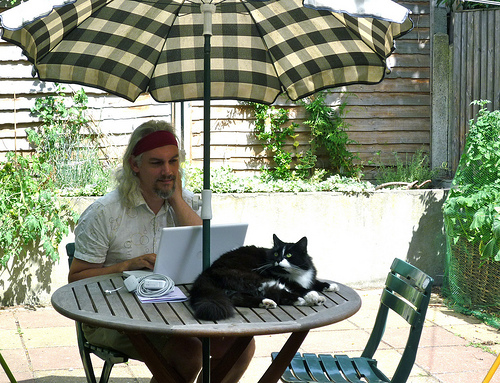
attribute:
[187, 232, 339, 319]
cat — laying, sitting, long haired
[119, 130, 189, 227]
man — wearing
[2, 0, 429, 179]
wall — wooden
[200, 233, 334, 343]
cat — alert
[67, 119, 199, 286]
man — sitting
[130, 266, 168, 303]
charger — laying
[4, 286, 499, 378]
pavers — red, brick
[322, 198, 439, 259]
wall — retaining, brick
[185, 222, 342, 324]
cat — black, white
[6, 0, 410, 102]
umbrella — green, white, plaid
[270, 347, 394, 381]
green chair — plastic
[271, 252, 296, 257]
eyes — green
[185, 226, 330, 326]
cat — furry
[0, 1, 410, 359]
umbrella — outdoor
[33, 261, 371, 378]
table — outdoor, brown, plastic